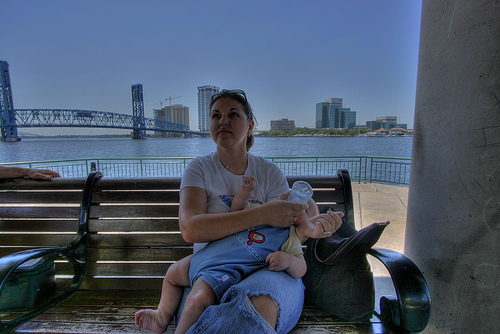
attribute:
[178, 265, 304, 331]
jeans — blue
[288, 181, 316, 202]
bottle — plastic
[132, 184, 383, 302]
baby — wearing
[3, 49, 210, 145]
bridge — metal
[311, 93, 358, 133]
building — distant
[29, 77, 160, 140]
bridge — metal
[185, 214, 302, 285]
onesie — blue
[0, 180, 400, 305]
bench — wooden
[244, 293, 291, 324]
jean — torn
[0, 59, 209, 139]
bridge — blue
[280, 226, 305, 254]
shirt — yellow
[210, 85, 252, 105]
sunglasses — black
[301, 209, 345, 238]
fingers — curled